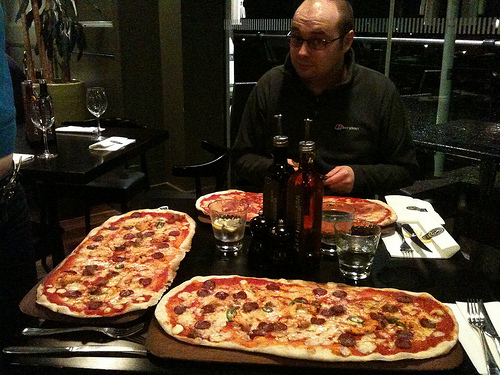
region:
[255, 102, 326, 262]
two brown liquor bottles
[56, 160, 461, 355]
three oblong baked pizzas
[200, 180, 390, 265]
three glasses with liquid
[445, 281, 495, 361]
fork and knife on napkin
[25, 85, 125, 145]
two empty wine glasses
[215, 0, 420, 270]
man sitting at table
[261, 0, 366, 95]
bald man wearing eyeglasses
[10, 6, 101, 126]
potted plant next to wall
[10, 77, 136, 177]
napkins on table by wall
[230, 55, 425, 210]
man wearing long sleeved shirt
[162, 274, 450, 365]
Huge pizza with toppings.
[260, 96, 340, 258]
tall oil and vinegar on table.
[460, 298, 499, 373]
silverware on white napkin.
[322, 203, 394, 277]
two drinking glasses on table.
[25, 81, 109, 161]
two wine glasses on table.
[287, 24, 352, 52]
glasses on mans face.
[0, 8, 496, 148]
man with glasses and green jacket.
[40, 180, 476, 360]
three pizzas on table.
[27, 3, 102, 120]
tree in restuarant back ground.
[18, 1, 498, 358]
dinner in a pizza restaurant.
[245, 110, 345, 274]
two bottles with spouts sitting on table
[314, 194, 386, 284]
Two glasses sitting on table.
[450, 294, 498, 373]
knife and fork resting on a napkin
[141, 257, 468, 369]
large oblong pizza resting on a wooden board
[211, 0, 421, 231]
man sitting in front of a pizza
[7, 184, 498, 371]
three large pizzas on a table.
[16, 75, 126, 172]
two wine glasses on a small table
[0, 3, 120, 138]
plant in an olive green planter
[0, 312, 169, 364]
fork and knife on a table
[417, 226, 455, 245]
sticker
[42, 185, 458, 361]
three pizzas on a table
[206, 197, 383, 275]
three clear glasses sitting on the table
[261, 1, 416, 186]
man wearing glasses and a black shirt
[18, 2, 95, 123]
plant in a green pot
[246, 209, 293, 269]
set of black salt and pepper shakers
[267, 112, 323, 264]
two tall glass bottles for olive oil and vinegar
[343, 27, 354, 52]
a man's ear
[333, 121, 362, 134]
Champion logo on the man's sweatshirt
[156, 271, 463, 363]
oblong-shaped pizza closest to the camera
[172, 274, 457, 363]
Long rectangular pizza with many toppings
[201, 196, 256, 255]
Glass of water with two slices of lemon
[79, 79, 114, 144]
Empty wine glass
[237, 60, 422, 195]
Champion brand black sweat shirt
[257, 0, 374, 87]
Balding man with glasses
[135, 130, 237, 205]
Empty brown wooden chair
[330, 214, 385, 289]
Half full water glass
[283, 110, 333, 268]
Olive oil bottle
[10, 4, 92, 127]
Planter with tree in it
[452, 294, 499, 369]
Clean fork and knife on napkin